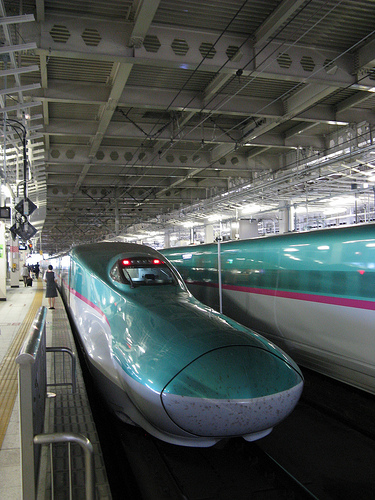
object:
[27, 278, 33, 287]
luggage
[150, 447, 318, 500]
railway track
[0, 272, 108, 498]
train platform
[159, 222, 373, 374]
train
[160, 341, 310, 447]
train front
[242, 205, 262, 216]
lights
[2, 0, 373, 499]
train station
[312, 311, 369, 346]
grey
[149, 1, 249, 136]
cables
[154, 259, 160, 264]
light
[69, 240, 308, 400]
train top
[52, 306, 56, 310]
shoes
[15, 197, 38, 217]
signs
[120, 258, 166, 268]
screen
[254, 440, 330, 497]
tracks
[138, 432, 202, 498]
tracks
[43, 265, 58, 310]
woman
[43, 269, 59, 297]
dress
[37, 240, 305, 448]
train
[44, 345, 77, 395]
railing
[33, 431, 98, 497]
railing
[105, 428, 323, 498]
train track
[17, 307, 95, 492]
safety railing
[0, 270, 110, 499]
sidewalk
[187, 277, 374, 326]
stripe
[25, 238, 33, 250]
traffic signal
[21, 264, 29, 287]
woman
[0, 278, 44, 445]
bumps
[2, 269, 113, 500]
platform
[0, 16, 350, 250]
roofing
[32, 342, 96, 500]
railing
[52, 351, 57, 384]
metal bar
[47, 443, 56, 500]
metal bar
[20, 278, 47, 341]
safety line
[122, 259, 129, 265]
headlights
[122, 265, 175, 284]
windshield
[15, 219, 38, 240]
signs